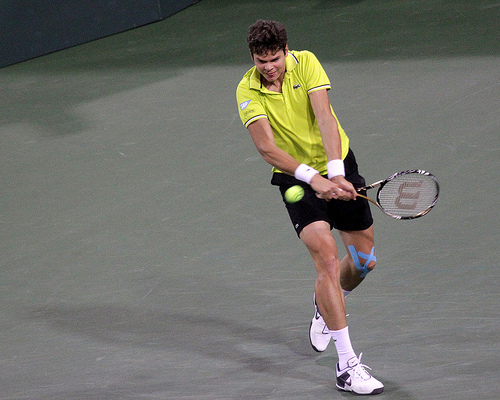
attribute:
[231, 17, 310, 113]
player — playing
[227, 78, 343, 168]
shirt — yellow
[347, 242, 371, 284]
stickers — blue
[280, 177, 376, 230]
shorts — black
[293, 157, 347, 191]
wristbands — white